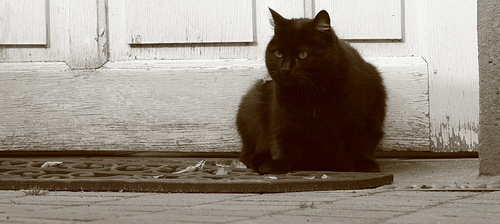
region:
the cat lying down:
[235, 7, 385, 173]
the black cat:
[235, 8, 385, 173]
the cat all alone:
[236, 7, 385, 176]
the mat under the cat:
[1, 157, 391, 189]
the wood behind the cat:
[0, 0, 477, 152]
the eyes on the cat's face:
[272, 49, 307, 58]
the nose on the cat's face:
[280, 61, 290, 72]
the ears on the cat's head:
[267, 6, 331, 34]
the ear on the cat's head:
[309, 9, 331, 34]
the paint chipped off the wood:
[428, 113, 480, 150]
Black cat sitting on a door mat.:
[0, 6, 393, 191]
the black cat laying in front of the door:
[231, 10, 387, 177]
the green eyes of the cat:
[269, 45, 311, 62]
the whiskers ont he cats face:
[296, 64, 330, 104]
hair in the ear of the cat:
[264, 2, 280, 30]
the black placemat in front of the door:
[0, 153, 387, 200]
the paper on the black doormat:
[9, 157, 240, 187]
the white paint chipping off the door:
[411, 97, 471, 155]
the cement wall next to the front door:
[469, 0, 499, 176]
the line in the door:
[414, 52, 442, 149]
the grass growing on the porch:
[16, 182, 59, 202]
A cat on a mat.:
[233, 5, 386, 175]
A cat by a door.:
[234, 5, 387, 175]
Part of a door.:
[0, 2, 477, 157]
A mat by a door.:
[0, 153, 396, 195]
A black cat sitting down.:
[234, 5, 390, 177]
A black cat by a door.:
[236, 4, 388, 174]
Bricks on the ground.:
[1, 188, 496, 221]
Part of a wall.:
[475, 0, 498, 174]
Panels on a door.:
[3, 0, 407, 48]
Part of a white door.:
[1, 0, 479, 155]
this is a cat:
[228, 9, 389, 158]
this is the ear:
[308, 7, 333, 22]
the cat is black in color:
[313, 75, 388, 141]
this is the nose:
[280, 62, 296, 72]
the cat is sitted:
[224, 5, 376, 158]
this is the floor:
[141, 143, 209, 215]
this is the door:
[87, 28, 188, 110]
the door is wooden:
[74, 25, 206, 106]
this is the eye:
[296, 48, 310, 60]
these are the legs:
[256, 143, 283, 168]